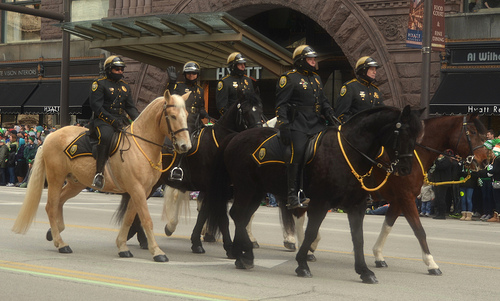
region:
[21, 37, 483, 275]
Police officers are riding horses.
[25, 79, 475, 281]
Four horses are visible in the photo.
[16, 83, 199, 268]
One horse is palomino colored.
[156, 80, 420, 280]
Two horses are black.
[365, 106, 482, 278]
One horse is brown.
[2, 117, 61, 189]
A crowd of people watch the horses.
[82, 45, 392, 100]
The riders are all wearing helmets.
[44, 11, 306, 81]
There is awning on the building.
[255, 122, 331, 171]
The saddle pads are black with orange trim.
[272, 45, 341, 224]
Each rider is dressed in black.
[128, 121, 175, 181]
yellow reins around horse's neck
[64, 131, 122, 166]
black and yellow saddle around horse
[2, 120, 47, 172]
spectators watching horses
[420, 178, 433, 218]
little kid wearing tan jacket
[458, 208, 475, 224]
woman wearing tan boots with felt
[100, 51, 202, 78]
policeman wearing black helmets with yellow section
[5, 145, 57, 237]
well groomed horse's tail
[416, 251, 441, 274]
white spot on horse's foot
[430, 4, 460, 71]
red banner on pole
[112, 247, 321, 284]
white marking on street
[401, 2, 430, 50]
blue, yellow and brown banner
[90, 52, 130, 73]
black and tan policeman's helmet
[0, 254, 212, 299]
blue and yellow line on street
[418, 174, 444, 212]
little girl wearing tan jacket and blue jeans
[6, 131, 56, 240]
fluffy tan horse's tail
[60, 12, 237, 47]
protruding green roof with partitions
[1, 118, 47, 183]
spectators watching the horses go by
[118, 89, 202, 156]
black reins on horses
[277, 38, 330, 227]
policeman wearing uniform with medals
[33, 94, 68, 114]
white signage on building front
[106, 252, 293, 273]
White arrow painted on the street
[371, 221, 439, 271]
White "socks" on the brown horse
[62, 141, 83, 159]
Emblem on the tan horse's saddle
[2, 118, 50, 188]
Cluster of onlookers behind the tan horse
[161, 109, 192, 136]
Bridle the tan horse is wearing on his face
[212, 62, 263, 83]
What can be seen of the HYATT sign behind the middle rider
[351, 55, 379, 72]
Helmet worn by the man on the brown horse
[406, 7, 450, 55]
Signs on top of the pole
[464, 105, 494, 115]
Smaller Hyatt sign behind the brown horse's head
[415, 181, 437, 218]
Child on the side of the street that can be seen just ahead of the brown horse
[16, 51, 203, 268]
police officer riding a caramel colored horse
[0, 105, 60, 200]
people watching parade from sidewalk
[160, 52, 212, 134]
police officer waving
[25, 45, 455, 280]
several police officers on horses in parade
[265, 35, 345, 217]
uniformed officer with helmet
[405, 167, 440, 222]
child on street watching parade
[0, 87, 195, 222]
horse with fancy saddle and rider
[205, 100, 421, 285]
dark brown horse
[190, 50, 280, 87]
Hyatt sign on building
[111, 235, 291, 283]
right turn lane sign painted on street